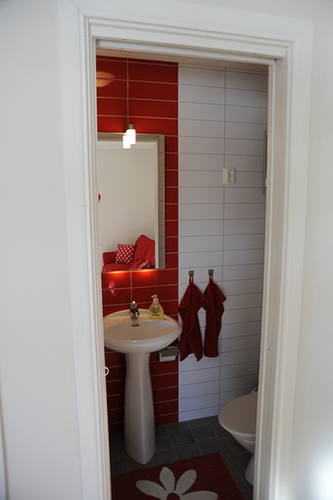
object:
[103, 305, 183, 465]
pedestal sink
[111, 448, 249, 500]
carpet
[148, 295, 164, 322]
hand soap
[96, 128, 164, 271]
mirror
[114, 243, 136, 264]
pillow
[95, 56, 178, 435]
red wall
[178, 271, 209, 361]
towel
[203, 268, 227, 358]
towel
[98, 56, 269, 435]
wall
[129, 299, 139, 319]
tap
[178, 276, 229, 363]
two towels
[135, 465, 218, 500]
flower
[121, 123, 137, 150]
light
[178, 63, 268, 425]
white wall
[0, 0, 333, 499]
bathroom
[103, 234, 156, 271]
red couch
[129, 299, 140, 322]
dmetal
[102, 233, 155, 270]
reflection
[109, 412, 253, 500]
floor